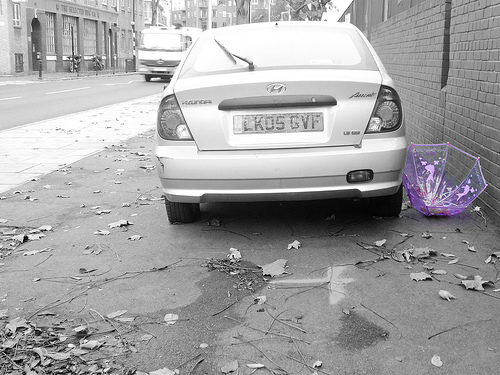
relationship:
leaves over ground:
[0, 130, 498, 374] [0, 92, 499, 374]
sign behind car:
[347, 91, 376, 99] [153, 20, 407, 224]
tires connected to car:
[164, 185, 402, 226] [153, 20, 407, 224]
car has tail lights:
[153, 20, 407, 224] [157, 85, 403, 140]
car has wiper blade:
[153, 20, 407, 224] [212, 37, 255, 70]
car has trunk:
[153, 20, 407, 224] [172, 71, 382, 152]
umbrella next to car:
[401, 141, 488, 218] [153, 20, 407, 224]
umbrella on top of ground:
[401, 141, 488, 218] [0, 92, 499, 374]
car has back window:
[153, 20, 407, 224] [178, 23, 379, 75]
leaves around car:
[0, 130, 498, 374] [153, 20, 407, 224]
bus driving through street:
[135, 22, 203, 82] [1, 73, 499, 374]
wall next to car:
[368, 0, 499, 224] [153, 20, 407, 224]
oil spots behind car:
[129, 259, 389, 374] [153, 20, 407, 224]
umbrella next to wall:
[401, 141, 488, 218] [368, 0, 499, 224]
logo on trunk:
[266, 84, 288, 97] [172, 71, 382, 152]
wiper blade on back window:
[212, 37, 255, 70] [178, 23, 379, 75]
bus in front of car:
[135, 22, 203, 82] [153, 20, 407, 224]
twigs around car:
[1, 187, 498, 374] [153, 20, 407, 224]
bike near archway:
[67, 55, 82, 70] [30, 16, 43, 70]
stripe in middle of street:
[1, 79, 141, 102] [1, 73, 499, 374]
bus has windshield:
[137, 23, 202, 83] [140, 33, 185, 53]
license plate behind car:
[232, 112, 324, 135] [153, 20, 407, 224]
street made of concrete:
[1, 73, 499, 374] [1, 75, 498, 375]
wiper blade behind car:
[212, 37, 255, 70] [153, 20, 407, 224]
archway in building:
[30, 16, 43, 70] [4, 0, 311, 99]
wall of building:
[368, 0, 499, 224] [343, 1, 499, 237]